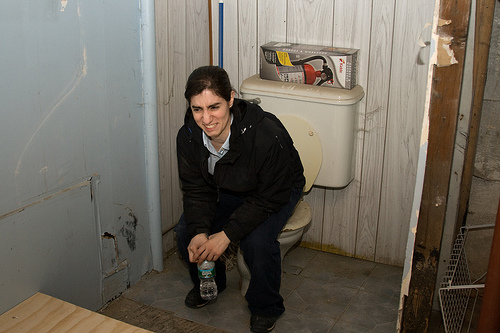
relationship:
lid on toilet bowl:
[275, 110, 320, 195] [234, 72, 359, 297]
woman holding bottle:
[164, 66, 303, 322] [196, 259, 217, 301]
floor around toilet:
[98, 244, 403, 327] [236, 68, 366, 303]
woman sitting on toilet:
[171, 65, 306, 333] [236, 68, 366, 303]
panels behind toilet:
[208, 0, 430, 270] [239, 70, 364, 280]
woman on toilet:
[164, 66, 303, 322] [236, 68, 366, 303]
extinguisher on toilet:
[262, 40, 353, 82] [230, 69, 361, 254]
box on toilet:
[259, 37, 364, 84] [213, 73, 344, 273]